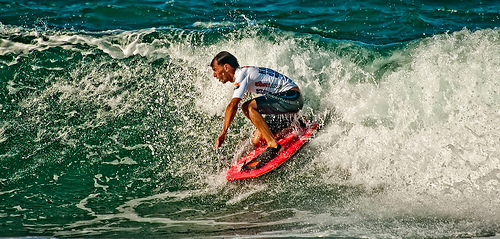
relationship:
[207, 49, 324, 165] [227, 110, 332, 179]
man standing on surfboard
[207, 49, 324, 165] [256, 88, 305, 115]
man wearing shorts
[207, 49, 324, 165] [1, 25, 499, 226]
man riding wave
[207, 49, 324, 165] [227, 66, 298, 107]
man wearing top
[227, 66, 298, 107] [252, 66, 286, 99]
top has writing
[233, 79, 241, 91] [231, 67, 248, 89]
emblem on shoulder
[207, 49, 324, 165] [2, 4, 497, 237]
man surfing in water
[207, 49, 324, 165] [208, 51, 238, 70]
man has hair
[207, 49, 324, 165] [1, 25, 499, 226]
man surfing wave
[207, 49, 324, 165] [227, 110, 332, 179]
man riding surfboard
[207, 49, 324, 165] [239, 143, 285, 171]
man wearing flipper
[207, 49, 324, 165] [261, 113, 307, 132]
man wearing flipper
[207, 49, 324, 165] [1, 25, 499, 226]
man looking surprised by wave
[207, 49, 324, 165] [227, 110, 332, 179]
man on surfboard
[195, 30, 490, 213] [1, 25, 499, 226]
foam of wave